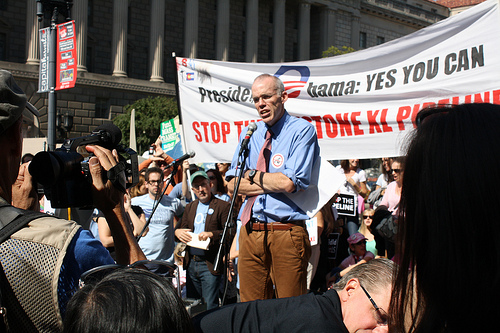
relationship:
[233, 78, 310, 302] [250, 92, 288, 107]
man wears glasses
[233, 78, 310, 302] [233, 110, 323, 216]
man wears shirt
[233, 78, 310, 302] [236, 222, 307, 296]
man wears pants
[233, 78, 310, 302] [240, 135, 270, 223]
man wears tie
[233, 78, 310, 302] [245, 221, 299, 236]
man wears belt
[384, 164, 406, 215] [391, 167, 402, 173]
person wears sunglasses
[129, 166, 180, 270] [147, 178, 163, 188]
man wears glasses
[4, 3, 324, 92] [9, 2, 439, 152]
columns on building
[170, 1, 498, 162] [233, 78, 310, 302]
banner behind man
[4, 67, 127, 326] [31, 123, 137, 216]
person uses camera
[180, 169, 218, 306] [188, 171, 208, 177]
man wears cap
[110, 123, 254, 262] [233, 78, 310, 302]
microphones near man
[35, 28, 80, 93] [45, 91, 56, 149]
banners on pole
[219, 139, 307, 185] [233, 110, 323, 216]
sleeves on shirt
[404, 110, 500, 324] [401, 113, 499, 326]
woman has hair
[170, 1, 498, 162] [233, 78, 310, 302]
sign behind man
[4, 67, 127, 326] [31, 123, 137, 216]
person has camera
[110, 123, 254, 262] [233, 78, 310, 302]
microphones in front of man